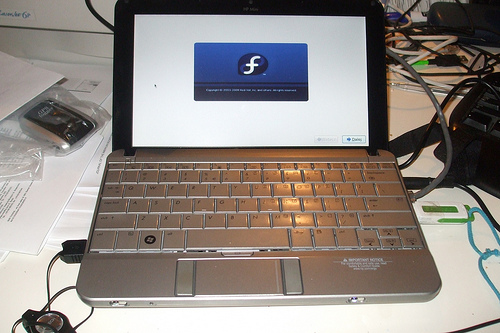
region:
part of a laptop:
[388, 284, 400, 296]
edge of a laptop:
[148, 286, 162, 296]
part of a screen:
[276, 125, 284, 131]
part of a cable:
[50, 285, 60, 295]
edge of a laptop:
[384, 177, 396, 189]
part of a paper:
[55, 214, 64, 224]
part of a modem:
[420, 210, 426, 226]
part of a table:
[254, 315, 266, 325]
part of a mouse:
[221, 205, 228, 240]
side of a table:
[405, 322, 416, 323]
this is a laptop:
[48, 12, 446, 307]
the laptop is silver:
[94, 134, 413, 329]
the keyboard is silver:
[96, 144, 403, 266]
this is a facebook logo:
[163, 28, 348, 115]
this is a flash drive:
[411, 194, 488, 239]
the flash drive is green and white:
[425, 191, 471, 242]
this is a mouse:
[16, 78, 96, 165]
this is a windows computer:
[83, 44, 355, 288]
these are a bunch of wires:
[407, 23, 487, 144]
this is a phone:
[452, 89, 498, 166]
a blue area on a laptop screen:
[180, 36, 335, 113]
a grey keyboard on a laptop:
[117, 161, 408, 266]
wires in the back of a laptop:
[392, 10, 482, 112]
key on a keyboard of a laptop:
[131, 147, 406, 253]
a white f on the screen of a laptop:
[191, 32, 365, 120]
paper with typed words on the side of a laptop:
[0, 136, 72, 243]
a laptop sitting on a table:
[24, 1, 471, 306]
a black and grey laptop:
[71, 0, 469, 285]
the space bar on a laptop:
[182, 222, 307, 254]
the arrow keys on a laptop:
[358, 219, 432, 254]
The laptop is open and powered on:
[67, 2, 447, 332]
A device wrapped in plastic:
[8, 80, 105, 162]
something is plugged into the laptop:
[12, 231, 84, 329]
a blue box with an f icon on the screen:
[183, 32, 325, 112]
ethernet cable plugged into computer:
[383, 24, 459, 204]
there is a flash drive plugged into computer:
[409, 200, 498, 236]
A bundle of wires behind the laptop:
[383, 4, 493, 109]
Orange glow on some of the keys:
[257, 151, 327, 245]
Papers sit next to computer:
[0, 113, 35, 245]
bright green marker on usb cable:
[409, 57, 436, 69]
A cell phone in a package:
[15, 83, 100, 168]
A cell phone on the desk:
[73, 13, 476, 330]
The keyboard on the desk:
[120, 174, 390, 239]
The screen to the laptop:
[101, 10, 401, 143]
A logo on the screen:
[177, 37, 324, 107]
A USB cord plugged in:
[413, 195, 475, 230]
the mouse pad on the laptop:
[181, 253, 296, 300]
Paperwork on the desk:
[1, 173, 84, 268]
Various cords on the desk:
[393, 0, 474, 129]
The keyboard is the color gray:
[104, 156, 419, 297]